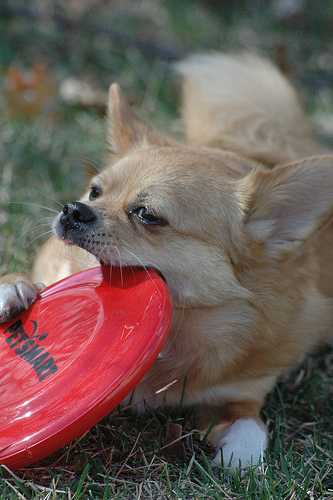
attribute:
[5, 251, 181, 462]
frisbee — red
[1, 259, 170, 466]
frisbee — red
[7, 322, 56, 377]
lettering — black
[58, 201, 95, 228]
nose — black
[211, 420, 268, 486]
paw — white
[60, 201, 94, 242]
nose — black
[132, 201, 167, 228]
eye — black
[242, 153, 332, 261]
ear — brown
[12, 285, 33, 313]
claw — clear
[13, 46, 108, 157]
grass — green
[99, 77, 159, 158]
ear — brown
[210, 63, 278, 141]
tail — furry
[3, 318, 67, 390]
word — black, petsmart